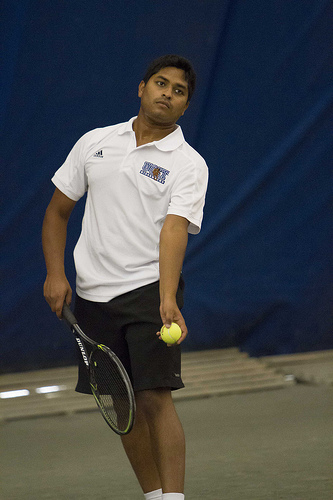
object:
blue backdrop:
[219, 22, 312, 210]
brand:
[75, 337, 90, 367]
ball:
[160, 322, 182, 344]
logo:
[138, 160, 170, 185]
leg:
[137, 388, 185, 492]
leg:
[111, 395, 163, 495]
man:
[40, 52, 209, 500]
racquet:
[60, 301, 137, 436]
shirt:
[51, 115, 210, 303]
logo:
[93, 150, 103, 159]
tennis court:
[0, 349, 333, 500]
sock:
[142, 488, 162, 500]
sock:
[161, 492, 185, 500]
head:
[138, 53, 197, 127]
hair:
[142, 53, 197, 105]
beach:
[139, 486, 189, 499]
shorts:
[72, 277, 185, 395]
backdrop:
[3, 2, 322, 356]